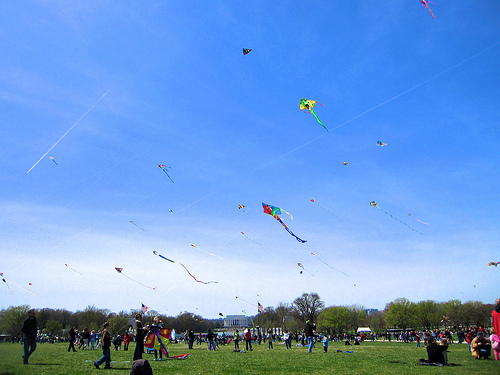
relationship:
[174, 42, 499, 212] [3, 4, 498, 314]
trail in sky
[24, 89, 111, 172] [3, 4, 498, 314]
trail in sky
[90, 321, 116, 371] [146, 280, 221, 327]
boy holds onto kite string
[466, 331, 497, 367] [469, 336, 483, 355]
person in jacket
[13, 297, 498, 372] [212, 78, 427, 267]
people gather to fly kites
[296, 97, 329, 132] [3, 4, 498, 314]
kite flying in sky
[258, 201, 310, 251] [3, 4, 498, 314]
kite flying in sky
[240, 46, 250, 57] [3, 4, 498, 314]
kite flying in sky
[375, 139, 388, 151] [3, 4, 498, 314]
kite flying in sky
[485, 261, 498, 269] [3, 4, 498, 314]
kite flying in sky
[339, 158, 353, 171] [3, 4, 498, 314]
kite flying in sky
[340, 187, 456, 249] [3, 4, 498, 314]
kite flying in sky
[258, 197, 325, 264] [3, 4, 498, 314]
kite flying in sky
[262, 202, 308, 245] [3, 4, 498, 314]
colorful kite flying in sky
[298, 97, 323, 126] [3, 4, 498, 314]
colorful kite flying in sky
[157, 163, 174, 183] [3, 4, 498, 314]
colorful kite flying in sky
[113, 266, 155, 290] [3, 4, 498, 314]
colorful kite flying in sky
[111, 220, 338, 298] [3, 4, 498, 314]
kite flying in sky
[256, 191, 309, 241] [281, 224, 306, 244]
kite has tail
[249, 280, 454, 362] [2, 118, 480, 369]
trees are in park